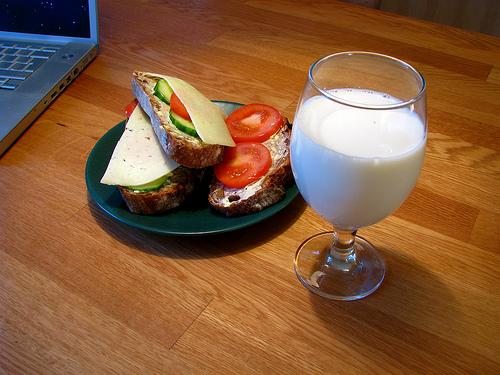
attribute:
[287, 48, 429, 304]
glass — goblet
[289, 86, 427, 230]
milk — white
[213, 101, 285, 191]
tomato — ripe, sliced in two pieces, red, sliced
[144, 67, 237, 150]
cheese — white, sliced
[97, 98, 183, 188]
cheese — white, sliced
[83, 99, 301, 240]
saucer — small, green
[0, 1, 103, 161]
laptop — silver, grqay, a computer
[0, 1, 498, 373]
table — wood, light wood, woode, brown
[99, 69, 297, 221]
food — sandwich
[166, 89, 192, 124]
tomato — red, sliced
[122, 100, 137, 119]
tomato — red, sliced